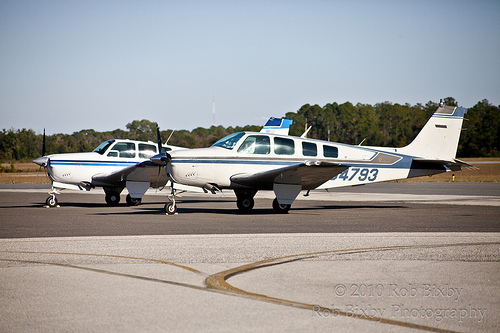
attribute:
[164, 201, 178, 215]
tire — small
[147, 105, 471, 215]
plane — white, small, blue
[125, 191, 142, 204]
tire — blak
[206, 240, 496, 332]
pattern — circular, curved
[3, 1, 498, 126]
sky — blue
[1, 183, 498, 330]
ground — painted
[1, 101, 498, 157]
trees — green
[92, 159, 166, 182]
wing — gray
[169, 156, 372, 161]
stripe — blue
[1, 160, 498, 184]
grass — parched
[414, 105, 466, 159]
stabilizer — white